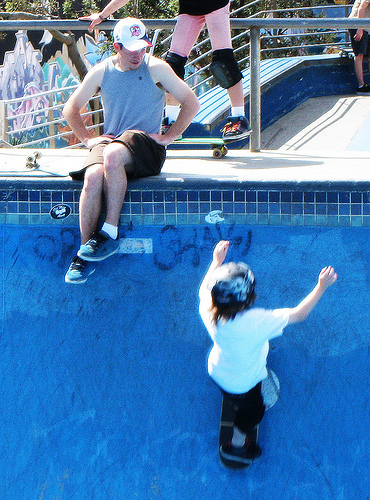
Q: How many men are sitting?
A: 1.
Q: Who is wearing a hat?
A: The man.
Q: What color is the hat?
A: White.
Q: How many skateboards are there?
A: 2.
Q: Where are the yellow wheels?
A: On the skateboard.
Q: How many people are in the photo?
A: 4.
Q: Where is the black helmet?
A: On the person's head.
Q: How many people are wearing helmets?
A: 1.